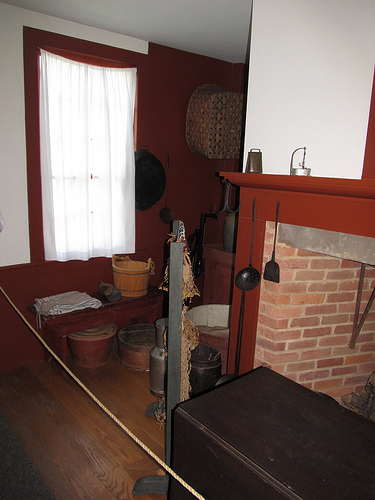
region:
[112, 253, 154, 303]
brown wooden basket with handles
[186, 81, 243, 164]
brown wicker on wall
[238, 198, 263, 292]
black cast iron spoon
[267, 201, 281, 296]
black cast iron shovel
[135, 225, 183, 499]
blue pained wood pole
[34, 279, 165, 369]
red stained wood bench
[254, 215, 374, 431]
red brick fireplace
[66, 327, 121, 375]
red terra cotta basket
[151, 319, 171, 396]
grey metal milk jug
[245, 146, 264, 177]
copper metal cow bell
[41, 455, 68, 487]
the floor is wooden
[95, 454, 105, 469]
the floor is wooden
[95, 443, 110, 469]
the floor is wooden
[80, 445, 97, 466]
the floor is wooden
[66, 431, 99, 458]
the floor is wooden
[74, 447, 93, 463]
the floor is wooden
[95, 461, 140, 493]
the floor is wooden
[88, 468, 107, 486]
the floor is wooden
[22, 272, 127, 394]
the cloth is white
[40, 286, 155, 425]
the cloth is white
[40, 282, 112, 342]
the cloth is white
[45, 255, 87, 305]
the cloth is white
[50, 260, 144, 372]
the cloth is white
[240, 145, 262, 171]
cow bell on fire mantle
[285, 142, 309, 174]
oil canter on fire mantle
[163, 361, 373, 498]
black hope chest next to fireplace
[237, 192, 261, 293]
cast iron ladle hanging on fire mantle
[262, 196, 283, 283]
fire scoop hanging from mantle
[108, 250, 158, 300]
wooden water pail on bench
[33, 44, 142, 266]
white curtains in window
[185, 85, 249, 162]
woven harvest basket on wall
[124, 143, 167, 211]
extra large cast iron pan on wall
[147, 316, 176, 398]
milk churn on floor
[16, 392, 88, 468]
Natural wood flooring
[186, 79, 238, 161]
Wicker basket hanging on the wall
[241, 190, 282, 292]
Fire utensils hanging on fireplace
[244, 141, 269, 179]
Cheese grater sitting on mantle of fireplace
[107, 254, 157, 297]
Wooden bucket sitting on a bench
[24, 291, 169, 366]
Wooden bench sitting on the floor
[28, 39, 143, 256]
Sheer curtain hanging in the window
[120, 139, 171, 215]
Metal pan hanging on the wall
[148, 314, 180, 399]
Old-fashioned metal jug or spittoon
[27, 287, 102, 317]
Folded cloth item sitting on a wooden bench